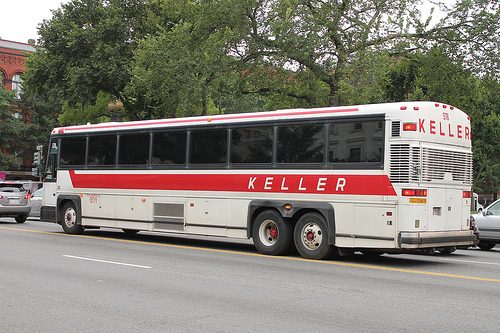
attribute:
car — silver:
[0, 180, 32, 222]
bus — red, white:
[109, 81, 464, 229]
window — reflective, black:
[65, 135, 365, 162]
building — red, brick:
[1, 33, 49, 174]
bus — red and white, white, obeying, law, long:
[37, 95, 479, 262]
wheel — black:
[293, 216, 328, 256]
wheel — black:
[253, 202, 285, 252]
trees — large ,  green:
[20, 0, 497, 110]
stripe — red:
[65, 104, 360, 139]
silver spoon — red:
[29, 90, 487, 260]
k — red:
[417, 116, 427, 133]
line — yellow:
[25, 228, 496, 294]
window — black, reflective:
[326, 109, 385, 172]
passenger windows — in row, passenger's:
[89, 132, 364, 215]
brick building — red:
[4, 38, 43, 163]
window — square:
[58, 135, 88, 172]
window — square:
[84, 130, 116, 171]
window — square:
[115, 127, 152, 169]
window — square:
[150, 123, 186, 170]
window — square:
[230, 121, 273, 163]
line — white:
[64, 252, 150, 274]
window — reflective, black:
[230, 124, 275, 164]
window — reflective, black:
[59, 135, 89, 167]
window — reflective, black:
[117, 130, 152, 166]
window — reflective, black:
[187, 129, 229, 164]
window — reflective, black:
[274, 121, 328, 166]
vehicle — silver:
[0, 180, 33, 222]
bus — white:
[38, 85, 468, 275]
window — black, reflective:
[323, 116, 389, 171]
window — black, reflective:
[147, 123, 190, 171]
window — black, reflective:
[81, 125, 120, 170]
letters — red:
[415, 115, 471, 140]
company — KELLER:
[247, 172, 349, 193]